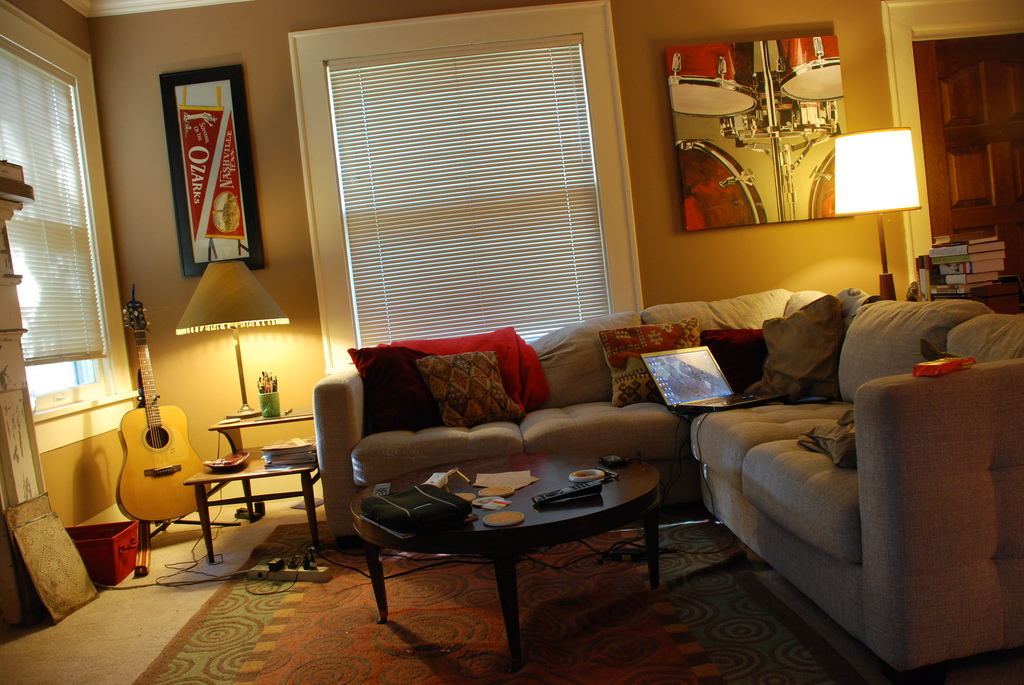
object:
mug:
[256, 390, 282, 422]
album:
[360, 511, 478, 540]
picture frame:
[157, 60, 266, 281]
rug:
[135, 519, 924, 685]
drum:
[665, 43, 758, 120]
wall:
[87, 0, 1023, 471]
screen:
[640, 349, 737, 407]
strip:
[97, 570, 250, 592]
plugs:
[308, 555, 318, 571]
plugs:
[287, 552, 299, 569]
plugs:
[268, 557, 285, 572]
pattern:
[268, 644, 375, 685]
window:
[0, 37, 135, 431]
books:
[925, 228, 990, 249]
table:
[930, 282, 1015, 317]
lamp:
[171, 258, 288, 419]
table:
[206, 405, 317, 456]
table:
[185, 447, 324, 568]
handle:
[118, 535, 139, 555]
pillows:
[419, 347, 524, 429]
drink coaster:
[484, 510, 526, 527]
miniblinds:
[0, 43, 105, 373]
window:
[321, 31, 619, 353]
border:
[0, 5, 95, 82]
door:
[911, 34, 1023, 306]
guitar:
[113, 282, 208, 521]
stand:
[113, 279, 213, 528]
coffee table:
[345, 451, 668, 664]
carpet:
[137, 517, 916, 685]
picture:
[157, 66, 272, 278]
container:
[61, 519, 146, 589]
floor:
[0, 471, 1020, 685]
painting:
[660, 18, 847, 234]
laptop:
[639, 346, 792, 414]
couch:
[310, 283, 1024, 676]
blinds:
[327, 40, 610, 350]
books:
[919, 285, 990, 296]